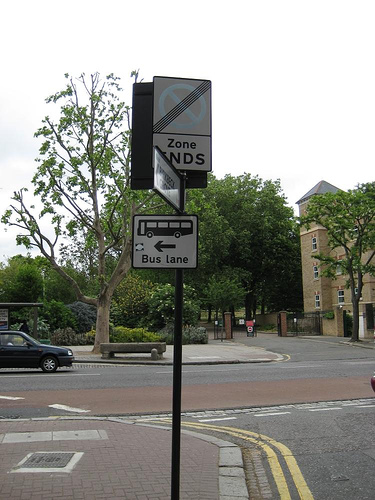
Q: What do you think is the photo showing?
A: It is showing a road.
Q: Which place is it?
A: It is a road.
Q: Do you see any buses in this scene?
A: Yes, there is a bus.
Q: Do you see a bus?
A: Yes, there is a bus.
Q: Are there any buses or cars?
A: Yes, there is a bus.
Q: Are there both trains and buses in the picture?
A: No, there is a bus but no trains.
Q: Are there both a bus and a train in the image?
A: No, there is a bus but no trains.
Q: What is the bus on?
A: The bus is on the sign.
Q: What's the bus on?
A: The bus is on the sign.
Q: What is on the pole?
A: The sign is on the pole.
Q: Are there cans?
A: No, there are no cans.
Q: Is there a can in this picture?
A: No, there are no cans.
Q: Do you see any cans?
A: No, there are no cans.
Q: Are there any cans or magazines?
A: No, there are no cans or magazines.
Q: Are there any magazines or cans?
A: No, there are no cans or magazines.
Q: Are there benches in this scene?
A: Yes, there is a bench.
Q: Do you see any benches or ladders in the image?
A: Yes, there is a bench.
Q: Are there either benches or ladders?
A: Yes, there is a bench.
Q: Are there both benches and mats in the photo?
A: No, there is a bench but no mats.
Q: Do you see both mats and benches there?
A: No, there is a bench but no mats.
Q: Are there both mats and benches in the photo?
A: No, there is a bench but no mats.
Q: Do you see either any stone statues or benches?
A: Yes, there is a stone bench.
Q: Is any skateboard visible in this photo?
A: No, there are no skateboards.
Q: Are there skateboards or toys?
A: No, there are no skateboards or toys.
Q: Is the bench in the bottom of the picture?
A: Yes, the bench is in the bottom of the image.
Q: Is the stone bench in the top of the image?
A: No, the bench is in the bottom of the image.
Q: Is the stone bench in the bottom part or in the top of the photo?
A: The bench is in the bottom of the image.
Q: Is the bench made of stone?
A: Yes, the bench is made of stone.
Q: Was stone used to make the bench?
A: Yes, the bench is made of stone.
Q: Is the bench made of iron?
A: No, the bench is made of stone.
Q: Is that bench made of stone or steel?
A: The bench is made of stone.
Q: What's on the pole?
A: The sign is on the pole.